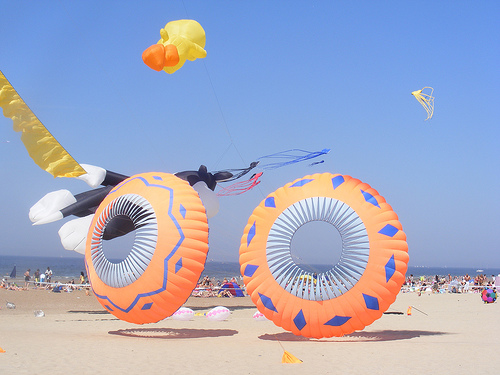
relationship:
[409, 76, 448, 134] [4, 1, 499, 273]
kite in sky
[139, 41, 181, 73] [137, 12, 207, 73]
feet on bird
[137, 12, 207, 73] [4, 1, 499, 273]
bird in sky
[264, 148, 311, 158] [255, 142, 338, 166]
streamer on kite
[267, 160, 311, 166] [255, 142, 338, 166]
streamer on kite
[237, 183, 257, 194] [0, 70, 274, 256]
streamer on kite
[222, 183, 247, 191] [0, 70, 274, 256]
streamer on kite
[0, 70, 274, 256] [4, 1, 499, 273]
kite in sky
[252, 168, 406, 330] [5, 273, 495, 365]
kite on beach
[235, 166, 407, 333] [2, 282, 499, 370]
kite on sand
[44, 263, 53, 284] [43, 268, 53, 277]
person wearing shirt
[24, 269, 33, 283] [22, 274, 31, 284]
person wearing shorts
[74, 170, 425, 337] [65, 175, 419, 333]
these are kites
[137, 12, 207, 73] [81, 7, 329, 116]
bird on air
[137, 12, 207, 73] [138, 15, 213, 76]
bird on air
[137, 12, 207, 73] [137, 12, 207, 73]
bird shaped like a bird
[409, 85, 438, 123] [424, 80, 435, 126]
kite with tails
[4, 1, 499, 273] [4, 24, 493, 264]
sky without clouds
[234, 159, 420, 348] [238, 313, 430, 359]
kite near ground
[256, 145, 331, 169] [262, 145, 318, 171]
kite with tails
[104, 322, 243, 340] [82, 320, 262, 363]
shadow cast onto ground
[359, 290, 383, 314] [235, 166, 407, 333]
shape on kite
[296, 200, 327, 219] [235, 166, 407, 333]
pattern on a kite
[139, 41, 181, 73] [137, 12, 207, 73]
feet on a bird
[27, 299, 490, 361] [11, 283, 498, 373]
sand at beach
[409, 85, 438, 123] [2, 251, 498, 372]
kite at beach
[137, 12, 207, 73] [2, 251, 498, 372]
bird at beach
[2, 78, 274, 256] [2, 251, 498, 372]
kite at beach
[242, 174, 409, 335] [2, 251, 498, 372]
kite at beach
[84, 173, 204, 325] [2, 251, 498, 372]
kite at beach